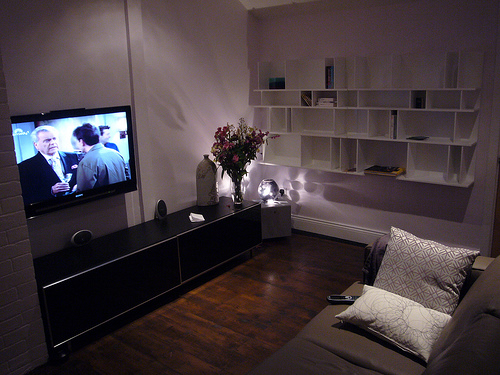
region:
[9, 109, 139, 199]
TV on a wall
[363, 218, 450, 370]
Pillows on a couch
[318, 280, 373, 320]
Remote on a couch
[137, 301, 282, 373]
Brown wood floor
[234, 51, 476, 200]
Shelves on a wall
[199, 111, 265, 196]
Flowers on a stand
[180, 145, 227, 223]
Vase on a stand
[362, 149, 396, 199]
Book on a shelf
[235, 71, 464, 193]
White shelf on a wall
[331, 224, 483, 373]
Couch in a living room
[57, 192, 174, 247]
Surround sound speakers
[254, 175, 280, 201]
Round vase in corner of room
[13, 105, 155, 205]
Television is on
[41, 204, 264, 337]
Long wood media cabinet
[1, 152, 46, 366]
Part of a brown brick wall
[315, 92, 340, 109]
Stack of books in a cubby hole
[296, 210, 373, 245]
Beveled wallboard trim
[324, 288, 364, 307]
Remote control next to a pillow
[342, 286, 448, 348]
Area pillow on seat of couch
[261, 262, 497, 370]
Brown leather sofa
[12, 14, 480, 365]
Picture of a living room.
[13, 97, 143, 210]
Tv mounted on wall.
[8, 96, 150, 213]
The tv is turned on.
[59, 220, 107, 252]
Sound speaker on the left.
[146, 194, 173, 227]
Sound speaker on the right.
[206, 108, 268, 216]
A vase of flowers.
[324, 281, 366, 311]
Remote control for the appliances.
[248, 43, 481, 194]
White shelving on the wall.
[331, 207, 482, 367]
Two square pillows on couch.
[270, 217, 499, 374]
A dark colored couch.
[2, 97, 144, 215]
Television on shows two men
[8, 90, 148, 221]
Television is mounted on wall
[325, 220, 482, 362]
Pillows on couch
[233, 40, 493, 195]
Shelves are white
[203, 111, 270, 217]
Vase has multicolor flowers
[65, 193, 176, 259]
Speakers on table are round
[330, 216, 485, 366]
Pillows are white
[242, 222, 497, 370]
Couch is brown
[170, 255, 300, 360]
Parquet floor is brown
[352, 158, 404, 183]
Book on white shelf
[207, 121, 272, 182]
Bouquet of multi-color flowers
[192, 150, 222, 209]
Tall pottery vase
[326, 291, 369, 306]
Remote control on cushion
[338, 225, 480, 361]
Decorative pillows on couch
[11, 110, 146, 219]
Flat screen TV mounted to wall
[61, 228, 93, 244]
Surround sound speaker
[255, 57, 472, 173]
Set of book shelves attached to wall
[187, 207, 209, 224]
Small white book on table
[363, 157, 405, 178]
Big book on a shelf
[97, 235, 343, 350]
Rich brown hardwood floors